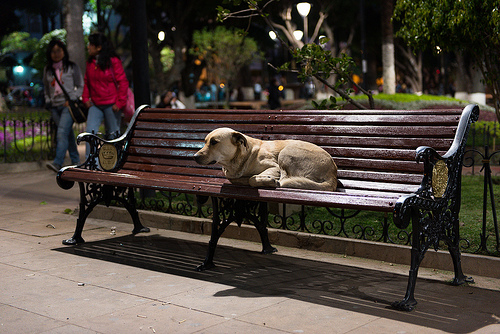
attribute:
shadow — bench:
[104, 227, 389, 296]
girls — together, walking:
[44, 30, 127, 175]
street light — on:
[290, 3, 310, 44]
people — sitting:
[154, 92, 192, 111]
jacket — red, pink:
[85, 63, 124, 105]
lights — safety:
[257, 3, 324, 51]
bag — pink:
[108, 71, 143, 116]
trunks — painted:
[373, 47, 412, 102]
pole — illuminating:
[298, 22, 318, 94]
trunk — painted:
[468, 66, 488, 111]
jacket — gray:
[41, 65, 76, 98]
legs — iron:
[198, 203, 473, 287]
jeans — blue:
[50, 112, 121, 154]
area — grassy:
[455, 157, 500, 220]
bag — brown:
[64, 93, 86, 125]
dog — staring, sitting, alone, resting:
[193, 125, 339, 202]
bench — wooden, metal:
[56, 105, 482, 307]